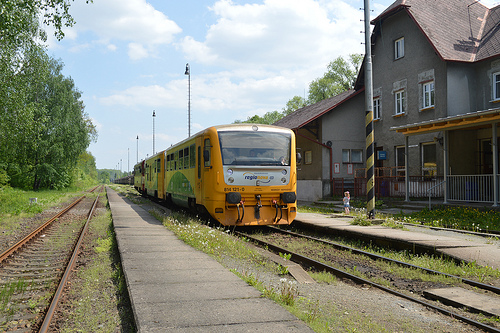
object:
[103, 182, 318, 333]
concrete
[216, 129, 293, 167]
window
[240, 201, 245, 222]
bumper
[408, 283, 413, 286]
rocks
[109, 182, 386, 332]
grass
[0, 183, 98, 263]
track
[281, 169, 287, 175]
headlight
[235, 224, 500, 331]
tracks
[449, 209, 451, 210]
yellow flowers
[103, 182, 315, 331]
sidewalk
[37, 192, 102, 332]
tracks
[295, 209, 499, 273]
sidewalk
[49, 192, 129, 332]
grass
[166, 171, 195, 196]
illustration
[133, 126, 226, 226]
side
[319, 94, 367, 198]
side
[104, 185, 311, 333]
section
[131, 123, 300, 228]
train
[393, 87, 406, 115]
window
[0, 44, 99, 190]
tree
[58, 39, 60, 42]
green leaves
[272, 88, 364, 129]
roof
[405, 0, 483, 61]
roof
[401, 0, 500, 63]
part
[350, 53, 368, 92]
part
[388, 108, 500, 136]
part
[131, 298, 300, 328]
panels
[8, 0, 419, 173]
blue sky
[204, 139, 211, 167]
window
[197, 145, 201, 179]
window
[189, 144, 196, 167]
window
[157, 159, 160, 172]
window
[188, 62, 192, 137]
pole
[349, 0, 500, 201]
building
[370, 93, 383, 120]
window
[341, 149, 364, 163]
window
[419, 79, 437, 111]
window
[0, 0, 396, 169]
cloud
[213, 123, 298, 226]
front